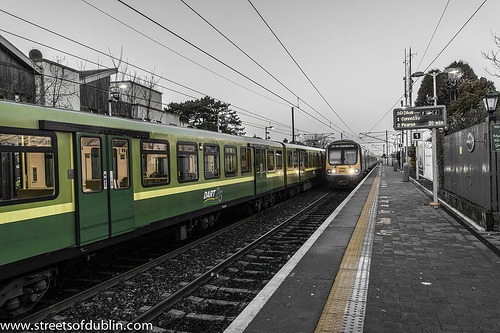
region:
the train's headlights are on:
[309, 130, 371, 192]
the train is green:
[0, 93, 325, 319]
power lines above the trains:
[1, 0, 365, 311]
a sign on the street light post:
[388, 64, 465, 214]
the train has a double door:
[57, 112, 149, 253]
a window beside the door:
[3, 122, 63, 212]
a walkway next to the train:
[224, 157, 498, 332]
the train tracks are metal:
[24, 185, 337, 331]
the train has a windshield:
[319, 135, 366, 184]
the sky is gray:
[1, 1, 499, 157]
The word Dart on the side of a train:
[203, 190, 216, 198]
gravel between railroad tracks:
[198, 247, 219, 259]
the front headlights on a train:
[330, 167, 355, 173]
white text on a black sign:
[393, 105, 443, 127]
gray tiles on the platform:
[402, 230, 445, 262]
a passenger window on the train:
[141, 140, 171, 185]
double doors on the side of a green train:
[72, 130, 131, 247]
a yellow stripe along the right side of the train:
[144, 190, 166, 196]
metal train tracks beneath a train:
[85, 262, 121, 284]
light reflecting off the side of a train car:
[443, 165, 470, 172]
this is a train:
[321, 135, 366, 182]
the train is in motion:
[323, 138, 363, 185]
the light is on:
[329, 167, 356, 174]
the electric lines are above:
[240, 67, 316, 116]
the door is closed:
[76, 136, 133, 238]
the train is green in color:
[164, 192, 186, 211]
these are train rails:
[211, 216, 262, 256]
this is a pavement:
[408, 232, 458, 317]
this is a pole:
[422, 132, 448, 202]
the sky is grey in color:
[351, 11, 387, 61]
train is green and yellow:
[0, 71, 315, 248]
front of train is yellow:
[318, 132, 363, 182]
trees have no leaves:
[1, 41, 173, 128]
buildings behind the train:
[0, 28, 201, 128]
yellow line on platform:
[309, 164, 381, 326]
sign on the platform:
[379, 92, 478, 137]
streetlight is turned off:
[478, 86, 499, 116]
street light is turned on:
[439, 54, 464, 88]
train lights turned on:
[319, 156, 373, 184]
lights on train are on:
[2, 129, 236, 189]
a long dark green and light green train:
[1, 96, 329, 284]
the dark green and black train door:
[73, 131, 110, 244]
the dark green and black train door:
[106, 128, 138, 238]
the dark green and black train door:
[252, 144, 262, 194]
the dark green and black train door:
[259, 146, 271, 191]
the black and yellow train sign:
[395, 106, 445, 131]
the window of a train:
[328, 148, 340, 164]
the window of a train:
[345, 150, 358, 167]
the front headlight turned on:
[329, 165, 337, 175]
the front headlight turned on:
[347, 167, 355, 177]